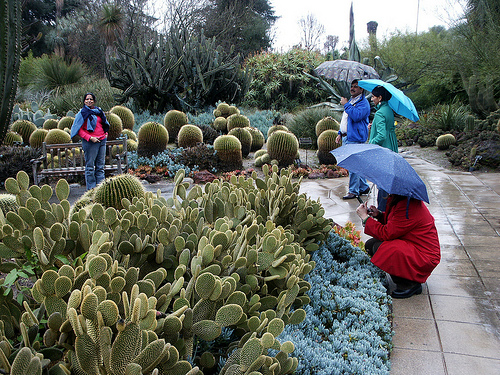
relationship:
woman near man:
[363, 84, 404, 147] [333, 77, 378, 155]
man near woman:
[333, 77, 378, 155] [363, 84, 404, 147]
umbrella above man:
[314, 56, 381, 86] [333, 77, 378, 155]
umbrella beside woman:
[314, 56, 381, 86] [363, 84, 404, 147]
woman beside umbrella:
[363, 84, 404, 147] [314, 56, 381, 86]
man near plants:
[333, 77, 378, 155] [1, 162, 320, 374]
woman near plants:
[363, 84, 404, 147] [1, 162, 320, 374]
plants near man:
[1, 162, 320, 374] [333, 77, 378, 155]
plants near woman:
[1, 162, 320, 374] [363, 84, 404, 147]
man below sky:
[333, 77, 378, 155] [141, 0, 488, 56]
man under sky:
[333, 77, 378, 155] [141, 0, 488, 56]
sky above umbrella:
[141, 0, 488, 56] [314, 56, 381, 86]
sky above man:
[141, 0, 488, 56] [333, 77, 378, 155]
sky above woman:
[141, 0, 488, 56] [363, 84, 404, 147]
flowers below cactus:
[291, 224, 394, 369] [3, 159, 325, 371]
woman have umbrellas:
[363, 84, 399, 153] [315, 57, 429, 204]